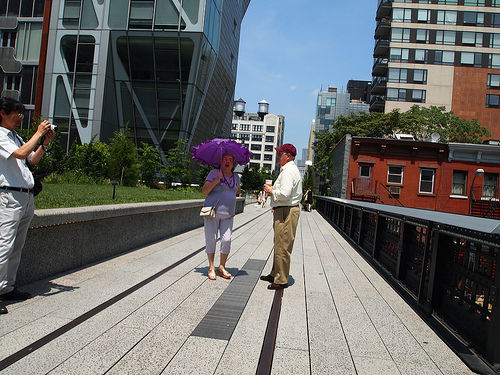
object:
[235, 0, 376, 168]
sky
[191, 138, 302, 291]
couple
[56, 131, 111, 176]
bush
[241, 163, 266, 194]
bush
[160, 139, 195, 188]
bush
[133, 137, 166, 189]
bush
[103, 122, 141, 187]
bush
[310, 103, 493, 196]
trees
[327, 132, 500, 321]
building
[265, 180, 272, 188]
coffee cup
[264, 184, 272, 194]
hand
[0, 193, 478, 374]
sidewalk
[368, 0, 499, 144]
building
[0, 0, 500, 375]
picture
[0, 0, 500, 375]
day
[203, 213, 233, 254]
pants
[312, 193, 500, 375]
rail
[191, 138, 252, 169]
edges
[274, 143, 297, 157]
cap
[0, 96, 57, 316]
man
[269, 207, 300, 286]
pants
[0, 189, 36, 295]
pants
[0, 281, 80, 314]
shadow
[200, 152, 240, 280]
lady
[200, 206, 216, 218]
purse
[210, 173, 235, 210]
strap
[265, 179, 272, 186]
coffee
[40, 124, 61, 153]
camera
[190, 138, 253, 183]
parasol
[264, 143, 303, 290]
man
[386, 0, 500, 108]
windows